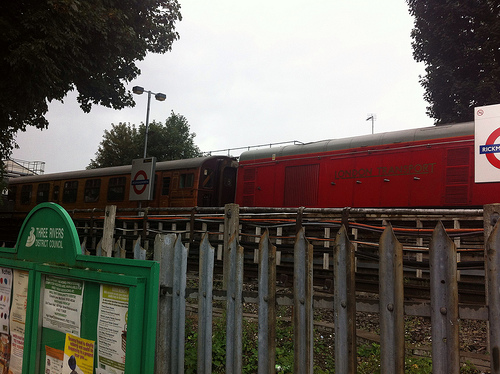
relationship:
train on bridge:
[7, 122, 499, 224] [116, 205, 496, 294]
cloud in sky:
[151, 57, 239, 114] [194, 12, 369, 94]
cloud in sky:
[0, 1, 423, 175] [189, 7, 423, 134]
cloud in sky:
[0, 1, 423, 175] [8, 0, 435, 172]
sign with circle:
[463, 102, 498, 189] [132, 167, 147, 196]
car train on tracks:
[235, 145, 480, 210] [2, 219, 494, 299]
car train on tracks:
[9, 157, 218, 220] [2, 219, 494, 299]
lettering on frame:
[22, 217, 61, 247] [2, 198, 165, 368]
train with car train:
[7, 122, 499, 224] [235, 122, 500, 210]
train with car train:
[7, 122, 499, 224] [3, 153, 237, 226]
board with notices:
[0, 199, 159, 373] [36, 274, 85, 335]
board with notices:
[0, 199, 159, 373] [93, 282, 133, 372]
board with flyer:
[0, 199, 159, 373] [60, 331, 97, 374]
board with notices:
[0, 199, 159, 373] [45, 346, 64, 373]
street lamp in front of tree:
[131, 82, 168, 157] [83, 107, 214, 171]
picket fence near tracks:
[0, 207, 498, 369] [3, 234, 494, 362]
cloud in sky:
[0, 1, 423, 175] [213, 29, 360, 123]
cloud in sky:
[0, 1, 423, 175] [280, 22, 367, 93]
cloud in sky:
[0, 1, 423, 175] [9, 4, 479, 188]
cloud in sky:
[0, 1, 423, 175] [47, 111, 87, 157]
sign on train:
[121, 154, 160, 202] [32, 73, 497, 296]